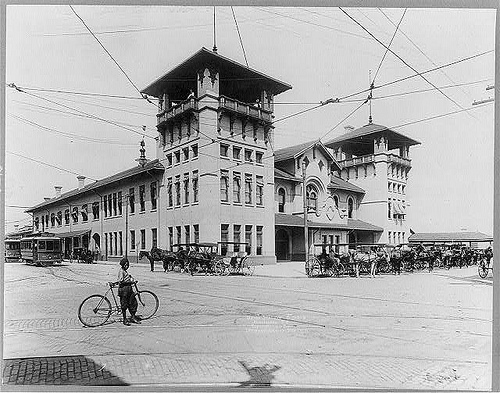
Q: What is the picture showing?
A: It is showing a street.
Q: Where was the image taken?
A: It was taken at the street.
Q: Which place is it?
A: It is a street.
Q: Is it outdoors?
A: Yes, it is outdoors.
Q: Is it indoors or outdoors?
A: It is outdoors.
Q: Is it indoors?
A: No, it is outdoors.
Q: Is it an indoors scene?
A: No, it is outdoors.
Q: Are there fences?
A: No, there are no fences.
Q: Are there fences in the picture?
A: No, there are no fences.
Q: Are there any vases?
A: No, there are no vases.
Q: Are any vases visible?
A: No, there are no vases.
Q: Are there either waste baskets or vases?
A: No, there are no vases or waste baskets.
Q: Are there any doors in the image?
A: Yes, there is a door.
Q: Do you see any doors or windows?
A: Yes, there is a door.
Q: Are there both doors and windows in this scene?
A: Yes, there are both a door and a window.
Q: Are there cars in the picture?
A: No, there are no cars.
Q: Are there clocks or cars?
A: No, there are no cars or clocks.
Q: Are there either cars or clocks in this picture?
A: No, there are no cars or clocks.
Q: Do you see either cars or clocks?
A: No, there are no cars or clocks.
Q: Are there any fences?
A: No, there are no fences.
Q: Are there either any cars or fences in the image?
A: No, there are no fences or cars.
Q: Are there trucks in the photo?
A: No, there are no trucks.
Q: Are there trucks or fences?
A: No, there are no trucks or fences.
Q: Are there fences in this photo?
A: No, there are no fences.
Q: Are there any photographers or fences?
A: No, there are no fences or photographers.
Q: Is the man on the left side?
A: Yes, the man is on the left of the image.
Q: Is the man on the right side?
A: No, the man is on the left of the image.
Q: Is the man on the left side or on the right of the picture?
A: The man is on the left of the image.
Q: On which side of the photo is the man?
A: The man is on the left of the image.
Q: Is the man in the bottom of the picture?
A: Yes, the man is in the bottom of the image.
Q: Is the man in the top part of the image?
A: No, the man is in the bottom of the image.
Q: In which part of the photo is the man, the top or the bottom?
A: The man is in the bottom of the image.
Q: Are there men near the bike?
A: Yes, there is a man near the bike.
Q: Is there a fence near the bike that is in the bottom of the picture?
A: No, there is a man near the bike.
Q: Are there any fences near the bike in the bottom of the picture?
A: No, there is a man near the bike.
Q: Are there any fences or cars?
A: No, there are no fences or cars.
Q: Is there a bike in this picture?
A: Yes, there is a bike.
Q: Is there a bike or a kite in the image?
A: Yes, there is a bike.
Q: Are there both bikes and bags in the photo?
A: No, there is a bike but no bags.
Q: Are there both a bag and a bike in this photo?
A: No, there is a bike but no bags.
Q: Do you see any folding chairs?
A: No, there are no folding chairs.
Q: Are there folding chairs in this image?
A: No, there are no folding chairs.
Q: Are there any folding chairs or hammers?
A: No, there are no folding chairs or hammers.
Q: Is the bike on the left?
A: Yes, the bike is on the left of the image.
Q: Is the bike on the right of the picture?
A: No, the bike is on the left of the image.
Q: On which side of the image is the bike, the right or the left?
A: The bike is on the left of the image.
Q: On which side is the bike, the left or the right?
A: The bike is on the left of the image.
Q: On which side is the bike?
A: The bike is on the left of the image.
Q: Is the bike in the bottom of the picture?
A: Yes, the bike is in the bottom of the image.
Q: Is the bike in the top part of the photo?
A: No, the bike is in the bottom of the image.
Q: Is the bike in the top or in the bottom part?
A: The bike is in the bottom of the image.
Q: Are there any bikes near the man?
A: Yes, there is a bike near the man.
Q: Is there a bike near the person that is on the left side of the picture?
A: Yes, there is a bike near the man.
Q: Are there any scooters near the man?
A: No, there is a bike near the man.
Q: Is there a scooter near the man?
A: No, there is a bike near the man.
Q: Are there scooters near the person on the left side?
A: No, there is a bike near the man.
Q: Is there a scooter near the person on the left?
A: No, there is a bike near the man.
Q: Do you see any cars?
A: No, there are no cars.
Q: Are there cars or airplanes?
A: No, there are no cars or airplanes.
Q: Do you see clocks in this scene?
A: No, there are no clocks.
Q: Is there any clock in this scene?
A: No, there are no clocks.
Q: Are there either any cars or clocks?
A: No, there are no clocks or cars.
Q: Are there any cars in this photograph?
A: No, there are no cars.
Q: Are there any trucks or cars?
A: No, there are no cars or trucks.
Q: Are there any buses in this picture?
A: No, there are no buses.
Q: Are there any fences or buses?
A: No, there are no buses or fences.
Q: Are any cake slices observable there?
A: No, there are no cake slices.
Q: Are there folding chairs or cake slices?
A: No, there are no cake slices or folding chairs.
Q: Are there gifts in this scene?
A: No, there are no gifts.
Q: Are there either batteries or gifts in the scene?
A: No, there are no gifts or batteries.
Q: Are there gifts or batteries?
A: No, there are no gifts or batteries.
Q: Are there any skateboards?
A: No, there are no skateboards.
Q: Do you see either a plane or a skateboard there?
A: No, there are no skateboards or airplanes.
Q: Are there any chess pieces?
A: No, there are no chess pieces.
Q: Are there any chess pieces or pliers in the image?
A: No, there are no chess pieces or pliers.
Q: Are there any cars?
A: No, there are no cars.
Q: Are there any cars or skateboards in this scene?
A: No, there are no cars or skateboards.